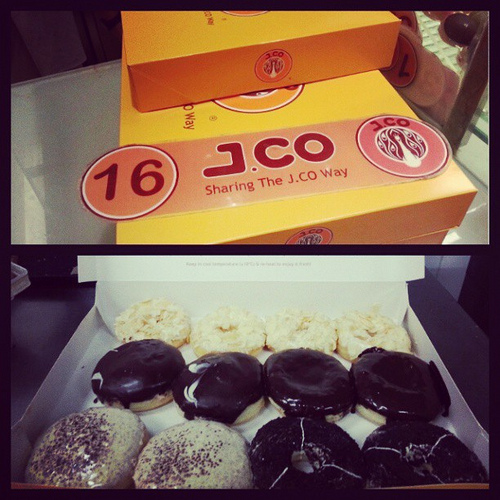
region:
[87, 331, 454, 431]
chocolate iced donuts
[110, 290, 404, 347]
white iced donuts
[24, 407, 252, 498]
white iced donuts with sprinkles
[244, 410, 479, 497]
black iced donuts with design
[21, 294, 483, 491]
assorted iced donuts in box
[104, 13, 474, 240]
closed box of assorted donuts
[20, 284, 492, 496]
donuts crowded into a box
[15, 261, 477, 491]
open box of donuts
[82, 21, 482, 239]
closed box of donuts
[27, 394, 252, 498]
pair of donuts without a hole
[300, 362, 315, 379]
CHOCLATE IS COVERING THE HOLE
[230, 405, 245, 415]
CHOCOLATE IS DRIPPING ALONG THE SIDE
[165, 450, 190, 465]
SPRINKLE ON THE TOP OF DOUNUT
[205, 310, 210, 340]
NUTS COVERING THE DOUNUTS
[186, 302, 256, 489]
THREE DIFFERENT FLAVORS OF DOUNUTS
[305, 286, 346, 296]
WHITE BOX HOLDING THE DOUNUTS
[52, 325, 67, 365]
BOX IS SITTING ON THE TABLE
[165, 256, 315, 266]
WRITING IS IN THE INSIDE OF THE BOX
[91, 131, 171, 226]
RED NUMBER 16 IS ON THE TOP OF BOX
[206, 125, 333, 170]
LOGO ON THE BOX IS J.CO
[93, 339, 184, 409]
first chocolate doughnut in the box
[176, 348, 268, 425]
second chocolate doughnut in the box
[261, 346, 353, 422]
third chocolate doughnut in the box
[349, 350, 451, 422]
fourth chocolate doughnut in the box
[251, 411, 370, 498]
fifth chocolate doughnut in the box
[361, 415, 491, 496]
sixth chocolate doughnut in the box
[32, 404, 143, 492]
first white doughnut with sprinkles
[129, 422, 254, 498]
second white doughnut with sprinkles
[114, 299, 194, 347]
first white doughnut with coconut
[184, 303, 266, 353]
second white doughnut with coconut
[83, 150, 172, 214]
a number on the box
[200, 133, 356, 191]
writing on the box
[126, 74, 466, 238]
a yellow cardboard box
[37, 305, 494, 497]
a box full of donuts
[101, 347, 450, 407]
chocolate frosted donuts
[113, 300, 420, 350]
white donuts in the back of the box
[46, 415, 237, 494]
white donuts with dark sprinkles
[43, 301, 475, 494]
a box of a dozen donuts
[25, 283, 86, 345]
the table under the donuts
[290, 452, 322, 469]
a hole in the donut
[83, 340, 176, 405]
a chocolate covered doughnut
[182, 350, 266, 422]
a chocolate covered doughnut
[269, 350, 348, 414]
a chocolate covered doughnut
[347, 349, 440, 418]
a chocolate covered doughnut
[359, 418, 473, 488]
a chocolate covered doughnut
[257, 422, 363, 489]
a chocolate covered doughnut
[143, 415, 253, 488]
a doughnut with icing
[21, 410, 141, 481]
a doughnut with icing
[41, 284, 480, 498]
a box of a dozen assorted doughnuts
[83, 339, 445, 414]
four chocolate covered doughnuts